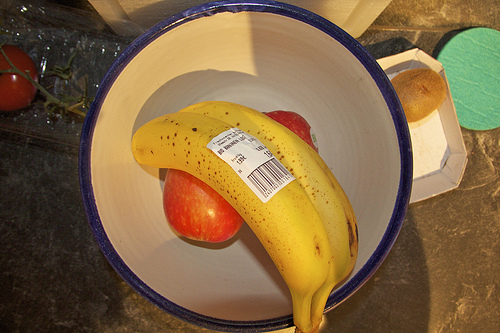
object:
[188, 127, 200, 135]
freckles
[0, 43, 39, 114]
tomato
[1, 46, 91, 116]
vine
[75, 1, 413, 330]
bowl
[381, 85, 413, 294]
blue rim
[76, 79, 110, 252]
blue rim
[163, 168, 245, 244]
apple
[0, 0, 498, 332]
marble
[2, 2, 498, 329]
counter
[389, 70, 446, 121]
kiwi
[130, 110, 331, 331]
banana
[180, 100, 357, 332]
banana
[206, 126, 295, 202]
sticker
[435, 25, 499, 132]
disk